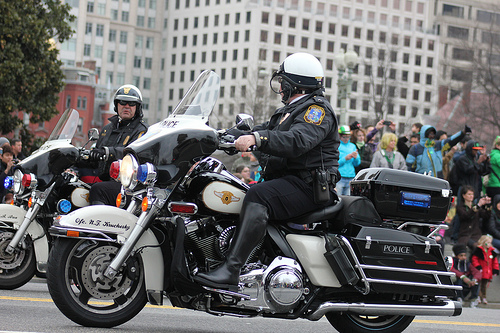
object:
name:
[75, 218, 131, 232]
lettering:
[384, 244, 411, 253]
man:
[74, 83, 154, 205]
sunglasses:
[117, 100, 138, 106]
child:
[471, 233, 500, 304]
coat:
[471, 246, 500, 280]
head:
[279, 52, 326, 105]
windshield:
[167, 69, 221, 124]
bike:
[46, 70, 463, 333]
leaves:
[0, 1, 75, 130]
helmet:
[113, 83, 144, 122]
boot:
[193, 201, 270, 292]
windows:
[232, 48, 239, 60]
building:
[0, 0, 500, 150]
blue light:
[57, 198, 72, 214]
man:
[192, 52, 342, 294]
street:
[0, 300, 500, 333]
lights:
[110, 152, 156, 212]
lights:
[3, 168, 38, 195]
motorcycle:
[0, 107, 106, 290]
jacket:
[95, 114, 150, 181]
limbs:
[482, 71, 498, 89]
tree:
[424, 0, 499, 148]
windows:
[76, 95, 88, 110]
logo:
[303, 105, 325, 126]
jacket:
[251, 88, 342, 201]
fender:
[46, 204, 164, 307]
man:
[405, 124, 472, 177]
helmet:
[269, 52, 325, 106]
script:
[75, 217, 131, 231]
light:
[136, 162, 157, 186]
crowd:
[336, 118, 500, 309]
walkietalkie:
[314, 146, 331, 203]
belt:
[299, 166, 338, 184]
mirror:
[219, 113, 255, 137]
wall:
[58, 90, 93, 122]